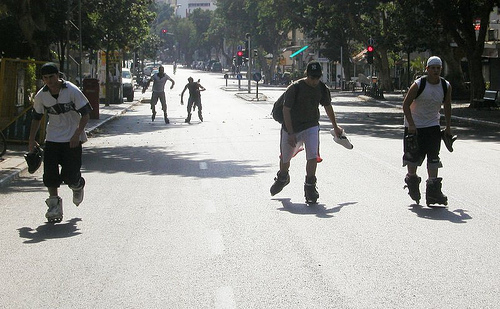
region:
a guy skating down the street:
[22, 56, 97, 228]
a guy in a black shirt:
[267, 62, 354, 205]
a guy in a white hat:
[400, 56, 456, 209]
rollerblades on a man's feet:
[401, 169, 452, 214]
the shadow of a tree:
[86, 142, 261, 179]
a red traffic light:
[232, 47, 247, 74]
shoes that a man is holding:
[329, 124, 356, 151]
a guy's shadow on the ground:
[16, 208, 83, 247]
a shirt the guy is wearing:
[30, 86, 93, 147]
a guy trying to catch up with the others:
[179, 74, 207, 126]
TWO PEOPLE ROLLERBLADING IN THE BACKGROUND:
[132, 56, 222, 128]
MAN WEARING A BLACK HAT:
[18, 58, 101, 234]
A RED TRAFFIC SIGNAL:
[229, 39, 249, 67]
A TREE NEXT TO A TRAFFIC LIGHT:
[361, 1, 437, 96]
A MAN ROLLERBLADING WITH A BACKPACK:
[261, 57, 355, 213]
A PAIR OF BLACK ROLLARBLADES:
[401, 168, 455, 213]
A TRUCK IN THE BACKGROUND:
[117, 68, 140, 105]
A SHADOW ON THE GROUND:
[259, 190, 363, 224]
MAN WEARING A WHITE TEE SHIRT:
[391, 48, 462, 211]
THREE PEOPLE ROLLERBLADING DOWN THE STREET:
[9, 56, 474, 229]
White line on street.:
[201, 225, 228, 256]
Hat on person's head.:
[301, 59, 323, 81]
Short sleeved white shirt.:
[28, 79, 90, 144]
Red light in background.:
[236, 49, 243, 57]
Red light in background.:
[363, 44, 376, 53]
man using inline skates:
[396, 51, 461, 213]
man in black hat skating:
[269, 52, 352, 210]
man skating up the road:
[23, 63, 98, 240]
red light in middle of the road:
[225, 43, 249, 68]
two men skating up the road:
[143, 65, 208, 132]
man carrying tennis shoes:
[327, 122, 357, 152]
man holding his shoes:
[425, 117, 477, 156]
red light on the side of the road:
[352, 35, 389, 110]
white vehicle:
[108, 63, 140, 110]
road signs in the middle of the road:
[218, 70, 274, 97]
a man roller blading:
[278, 58, 329, 218]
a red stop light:
[230, 46, 248, 91]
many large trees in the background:
[243, 0, 479, 105]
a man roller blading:
[20, 52, 96, 223]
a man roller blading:
[390, 60, 458, 225]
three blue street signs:
[210, 70, 265, 100]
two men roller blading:
[140, 65, 206, 125]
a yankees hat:
[307, 61, 322, 81]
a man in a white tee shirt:
[402, 51, 460, 213]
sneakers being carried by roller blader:
[323, 122, 356, 152]